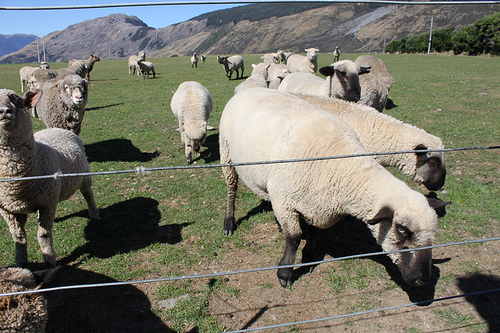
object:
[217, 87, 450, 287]
sheep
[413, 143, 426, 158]
ear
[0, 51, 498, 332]
grass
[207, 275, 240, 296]
patch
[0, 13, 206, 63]
mountain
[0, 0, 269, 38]
sky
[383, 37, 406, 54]
shrubbery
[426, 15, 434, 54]
pole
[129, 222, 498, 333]
soil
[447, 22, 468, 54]
trees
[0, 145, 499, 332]
fence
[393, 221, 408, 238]
eye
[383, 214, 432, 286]
face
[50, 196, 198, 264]
shadow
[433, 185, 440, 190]
nose